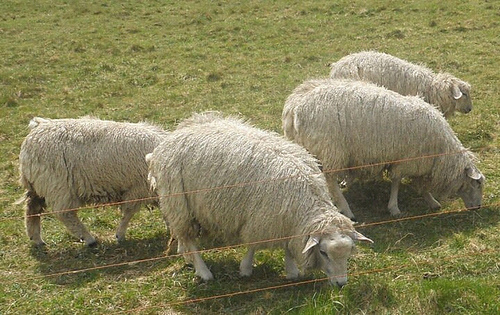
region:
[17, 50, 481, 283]
four sheep in the pasture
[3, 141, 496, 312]
wire fence in front of sheep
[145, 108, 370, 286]
front sheep is white and very woolly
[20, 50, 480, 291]
the sheep are all grazing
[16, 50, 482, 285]
all the sheep are white and woolly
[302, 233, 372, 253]
the front sheep has two long ears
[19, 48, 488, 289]
four sheeps on a field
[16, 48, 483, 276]
big fat sheeps eating grass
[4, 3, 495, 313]
grass is green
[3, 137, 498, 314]
orange metal fence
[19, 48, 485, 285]
big wollly sheeps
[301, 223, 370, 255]
teo small white ears of sheep in front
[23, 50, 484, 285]
wooly sheeps standing together in a field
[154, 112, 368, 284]
white sheep in green field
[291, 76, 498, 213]
white sheep in green field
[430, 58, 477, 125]
white sheep in green field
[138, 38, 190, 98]
short green and brown grass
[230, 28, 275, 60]
short green and brown grass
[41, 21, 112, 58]
short green and brown grass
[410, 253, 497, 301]
short green and brown grass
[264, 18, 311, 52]
short green and brown grass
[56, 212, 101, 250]
white leg of sheep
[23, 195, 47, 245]
white leg of sheep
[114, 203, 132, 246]
white leg of sheep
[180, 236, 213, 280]
white leg of sheep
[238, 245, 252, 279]
white leg of sheep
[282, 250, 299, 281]
white leg of sheep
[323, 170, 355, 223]
white leg of sheep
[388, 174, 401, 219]
white leg of sheep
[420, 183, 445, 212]
white leg of sheep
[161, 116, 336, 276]
Sheep with white woolly fur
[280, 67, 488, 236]
Sheep with white woolly fur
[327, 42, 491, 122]
Sheep with white woolly fur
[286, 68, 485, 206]
Sheep with white woolly fur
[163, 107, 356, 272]
Sheep with white woolly fur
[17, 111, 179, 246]
Sheep with white woolly fur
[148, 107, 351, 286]
Sheep with white woolly fur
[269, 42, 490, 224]
Sheep with white woolly fur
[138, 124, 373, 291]
Sheep with white woolly fur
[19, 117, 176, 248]
White sheep with no visible head.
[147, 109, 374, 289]
The largest white sheep.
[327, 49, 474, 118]
The smallest sheep.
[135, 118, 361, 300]
sheep in a field eating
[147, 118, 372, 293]
sheep is eating grass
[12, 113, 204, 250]
sheep is eating grass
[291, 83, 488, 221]
sheep is eating grass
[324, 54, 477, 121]
sheep is eating grass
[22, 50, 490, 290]
sheep are gathered in field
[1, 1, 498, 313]
field is underneath sheep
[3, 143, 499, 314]
fence keeps sheep in field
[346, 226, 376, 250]
ear of sheep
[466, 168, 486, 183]
ear of sheep on head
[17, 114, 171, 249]
sheep grazing behind fence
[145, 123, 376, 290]
sheep grazing behind fence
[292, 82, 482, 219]
sheep grazing behind fence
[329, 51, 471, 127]
sheep grazing behind fence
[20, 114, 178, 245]
white sheep is fluffy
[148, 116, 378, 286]
white sheep is fluffy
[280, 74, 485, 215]
white sheep is fluffy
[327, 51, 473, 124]
white sheep is fluffy